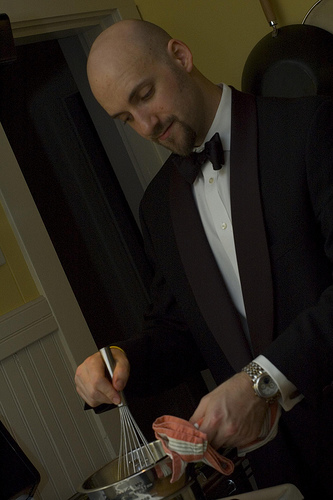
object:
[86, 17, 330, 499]
man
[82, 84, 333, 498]
tux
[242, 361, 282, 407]
watch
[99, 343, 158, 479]
whisk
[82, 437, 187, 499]
pot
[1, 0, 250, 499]
doorway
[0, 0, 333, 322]
background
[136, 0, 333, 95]
wall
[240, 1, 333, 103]
pan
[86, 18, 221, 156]
head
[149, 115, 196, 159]
goatee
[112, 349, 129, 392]
thumb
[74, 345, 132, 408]
hand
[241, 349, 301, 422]
wrist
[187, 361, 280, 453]
hand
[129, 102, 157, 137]
nose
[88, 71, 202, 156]
face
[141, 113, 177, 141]
mustache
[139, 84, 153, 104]
eye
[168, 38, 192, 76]
ear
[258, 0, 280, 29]
handle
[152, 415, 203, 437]
orange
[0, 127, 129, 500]
lines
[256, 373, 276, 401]
circles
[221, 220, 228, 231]
buttons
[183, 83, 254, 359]
shirt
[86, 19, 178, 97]
bald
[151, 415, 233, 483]
kitchen towel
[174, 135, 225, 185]
bowtie